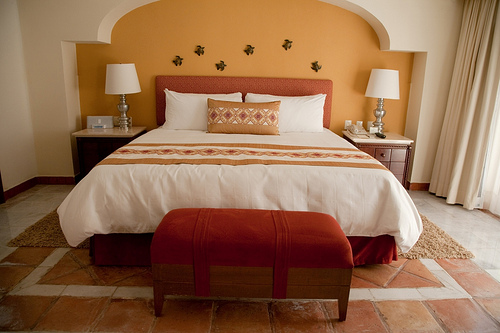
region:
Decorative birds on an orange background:
[150, 31, 339, 80]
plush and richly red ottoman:
[139, 200, 359, 324]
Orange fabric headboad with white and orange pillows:
[148, 72, 337, 137]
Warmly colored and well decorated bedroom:
[7, 7, 493, 321]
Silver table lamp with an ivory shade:
[98, 58, 145, 135]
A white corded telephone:
[346, 120, 365, 137]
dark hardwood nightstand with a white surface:
[345, 126, 410, 206]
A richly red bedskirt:
[82, 225, 419, 274]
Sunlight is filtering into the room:
[4, 3, 496, 327]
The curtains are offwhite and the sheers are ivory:
[462, 20, 498, 231]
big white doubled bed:
[53, 74, 428, 251]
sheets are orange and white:
[58, 116, 420, 258]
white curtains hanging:
[430, 5, 498, 213]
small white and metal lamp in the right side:
[361, 63, 402, 137]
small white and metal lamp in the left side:
[102, 61, 142, 126]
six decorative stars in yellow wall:
[165, 39, 319, 77]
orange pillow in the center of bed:
[208, 98, 278, 135]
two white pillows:
[164, 89, 324, 127]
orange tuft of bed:
[152, 71, 330, 132]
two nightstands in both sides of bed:
[67, 121, 415, 199]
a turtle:
[275, 37, 294, 52]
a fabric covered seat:
[143, 202, 376, 326]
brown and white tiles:
[11, 251, 130, 327]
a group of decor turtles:
[166, 30, 323, 82]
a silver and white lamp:
[361, 65, 407, 131]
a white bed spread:
[113, 92, 380, 229]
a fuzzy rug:
[403, 199, 473, 261]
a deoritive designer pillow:
[206, 92, 280, 134]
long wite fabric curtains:
[421, 0, 498, 202]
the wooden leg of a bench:
[331, 290, 348, 326]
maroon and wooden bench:
[141, 203, 358, 317]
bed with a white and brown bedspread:
[82, 71, 422, 263]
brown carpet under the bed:
[8, 198, 85, 257]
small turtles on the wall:
[159, 28, 335, 85]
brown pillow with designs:
[205, 98, 285, 136]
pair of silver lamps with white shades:
[97, 60, 402, 138]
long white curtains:
[431, 3, 495, 208]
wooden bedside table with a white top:
[68, 113, 140, 182]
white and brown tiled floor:
[14, 259, 478, 331]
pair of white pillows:
[154, 85, 328, 131]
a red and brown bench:
[147, 204, 357, 324]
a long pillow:
[205, 98, 287, 138]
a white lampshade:
[362, 61, 404, 101]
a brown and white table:
[344, 123, 413, 183]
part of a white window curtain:
[425, 0, 494, 217]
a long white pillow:
[157, 86, 242, 132]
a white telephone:
[348, 118, 368, 137]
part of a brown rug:
[412, 203, 476, 261]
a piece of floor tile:
[375, 298, 438, 332]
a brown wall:
[75, 10, 414, 143]